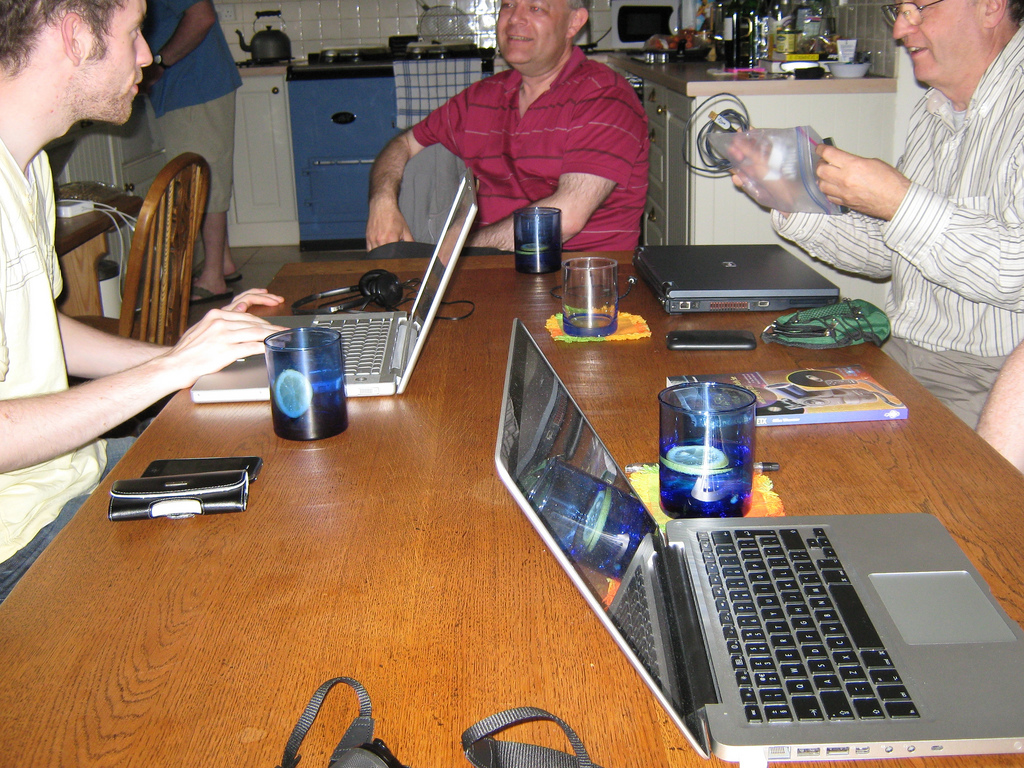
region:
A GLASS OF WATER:
[653, 375, 762, 524]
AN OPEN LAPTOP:
[490, 309, 1018, 763]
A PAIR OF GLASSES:
[873, 0, 959, 36]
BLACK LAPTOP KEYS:
[689, 513, 928, 732]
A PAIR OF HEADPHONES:
[283, 263, 414, 321]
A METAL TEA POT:
[226, 23, 297, 66]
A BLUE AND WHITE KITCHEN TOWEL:
[387, 54, 493, 137]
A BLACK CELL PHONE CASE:
[103, 465, 256, 527]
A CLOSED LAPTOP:
[631, 235, 850, 318]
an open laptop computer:
[494, 314, 1022, 764]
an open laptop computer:
[184, 171, 476, 409]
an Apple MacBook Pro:
[491, 317, 1016, 767]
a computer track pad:
[866, 566, 1010, 643]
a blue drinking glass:
[655, 378, 754, 514]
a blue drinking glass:
[260, 329, 346, 440]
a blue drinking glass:
[514, 203, 563, 273]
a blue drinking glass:
[560, 255, 617, 339]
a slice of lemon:
[667, 441, 726, 474]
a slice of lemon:
[273, 369, 311, 420]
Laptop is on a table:
[488, 305, 1020, 765]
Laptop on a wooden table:
[472, 298, 1014, 763]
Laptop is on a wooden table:
[481, 308, 1017, 762]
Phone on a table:
[137, 441, 270, 490]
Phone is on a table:
[131, 447, 275, 487]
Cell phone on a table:
[136, 440, 283, 494]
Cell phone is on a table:
[134, 446, 278, 494]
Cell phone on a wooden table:
[138, 443, 266, 489]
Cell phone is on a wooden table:
[134, 446, 265, 486]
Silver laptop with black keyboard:
[494, 305, 1023, 762]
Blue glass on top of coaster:
[655, 381, 755, 515]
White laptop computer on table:
[187, 178, 479, 404]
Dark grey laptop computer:
[633, 242, 843, 315]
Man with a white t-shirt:
[1, 3, 287, 585]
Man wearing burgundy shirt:
[361, 2, 657, 265]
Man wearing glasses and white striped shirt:
[712, 1, 1023, 397]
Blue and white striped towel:
[388, 53, 483, 134]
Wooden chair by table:
[121, 151, 213, 347]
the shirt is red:
[406, 47, 645, 248]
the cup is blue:
[661, 384, 754, 514]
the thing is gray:
[279, 676, 397, 763]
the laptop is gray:
[491, 319, 1022, 756]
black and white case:
[112, 466, 248, 512]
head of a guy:
[0, 0, 152, 124]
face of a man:
[889, 5, 948, 82]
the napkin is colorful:
[547, 308, 646, 340]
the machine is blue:
[289, 62, 397, 249]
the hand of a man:
[137, 282, 312, 372]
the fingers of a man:
[207, 294, 291, 372]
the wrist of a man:
[134, 344, 198, 382]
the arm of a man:
[23, 364, 178, 448]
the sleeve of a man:
[877, 206, 1020, 302]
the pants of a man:
[889, 318, 1020, 435]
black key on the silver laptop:
[756, 681, 783, 700]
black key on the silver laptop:
[747, 653, 771, 673]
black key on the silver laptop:
[738, 634, 771, 655]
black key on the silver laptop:
[737, 624, 766, 644]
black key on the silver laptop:
[785, 691, 820, 724]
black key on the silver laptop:
[811, 668, 837, 694]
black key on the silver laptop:
[817, 684, 846, 720]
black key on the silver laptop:
[762, 631, 800, 651]